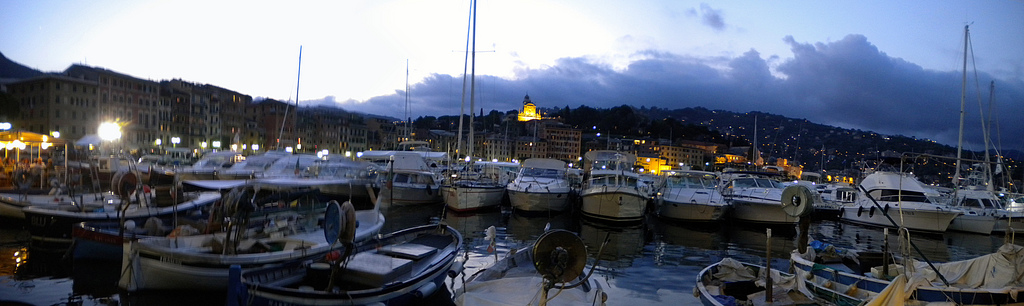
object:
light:
[510, 94, 546, 125]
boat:
[495, 114, 580, 215]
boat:
[431, 0, 508, 216]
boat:
[689, 254, 876, 305]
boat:
[777, 245, 1020, 302]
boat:
[784, 225, 1023, 306]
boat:
[6, 177, 248, 236]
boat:
[172, 146, 270, 207]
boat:
[375, 154, 440, 206]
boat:
[514, 155, 575, 218]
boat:
[249, 44, 384, 202]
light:
[81, 108, 137, 146]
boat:
[566, 158, 653, 239]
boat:
[651, 163, 735, 224]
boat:
[721, 175, 815, 229]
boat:
[843, 163, 985, 241]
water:
[0, 256, 92, 306]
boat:
[121, 200, 390, 289]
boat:
[230, 219, 468, 302]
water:
[476, 182, 985, 302]